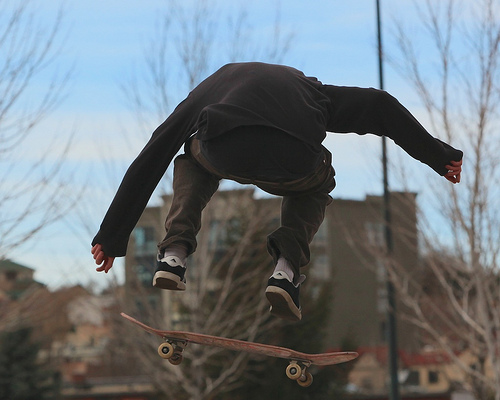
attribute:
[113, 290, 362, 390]
skateboard — dirty, mid air, red, dingy, brown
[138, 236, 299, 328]
shoes — white, black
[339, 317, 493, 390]
building — tan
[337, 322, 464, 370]
roof — red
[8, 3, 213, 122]
trees — bare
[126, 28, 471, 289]
skateboarder — jumping, mid air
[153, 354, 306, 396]
wheels — beige, yellow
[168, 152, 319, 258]
pants — brown, sagging, dark, cuffed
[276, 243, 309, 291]
socks — white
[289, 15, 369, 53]
sky — blue, cloudy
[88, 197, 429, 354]
building — brown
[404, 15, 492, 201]
tree — bare, short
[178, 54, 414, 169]
top — black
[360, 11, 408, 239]
pole — tall, black, metal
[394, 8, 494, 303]
tree — bare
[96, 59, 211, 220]
sleeves — long, black